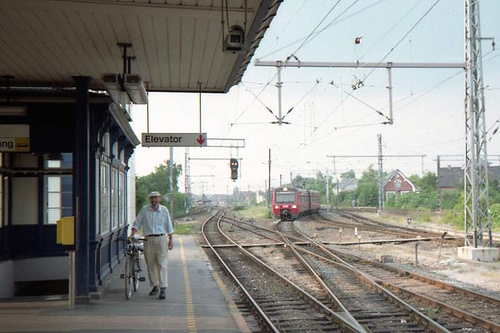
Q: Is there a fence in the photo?
A: No, there are no fences.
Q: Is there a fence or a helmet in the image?
A: No, there are no fences or helmets.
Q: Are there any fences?
A: No, there are no fences.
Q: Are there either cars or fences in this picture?
A: No, there are no fences or cars.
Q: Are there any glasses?
A: No, there are no glasses.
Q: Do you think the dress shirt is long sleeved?
A: Yes, the dress shirt is long sleeved.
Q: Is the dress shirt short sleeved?
A: No, the dress shirt is long sleeved.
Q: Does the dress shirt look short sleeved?
A: No, the dress shirt is long sleeved.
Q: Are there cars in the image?
A: No, there are no cars.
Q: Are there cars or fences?
A: No, there are no cars or fences.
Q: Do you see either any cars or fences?
A: No, there are no cars or fences.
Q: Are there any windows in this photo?
A: Yes, there are windows.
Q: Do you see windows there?
A: Yes, there are windows.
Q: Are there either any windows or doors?
A: Yes, there are windows.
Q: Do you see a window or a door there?
A: Yes, there are windows.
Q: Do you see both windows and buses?
A: No, there are windows but no buses.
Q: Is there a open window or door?
A: Yes, there are open windows.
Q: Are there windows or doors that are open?
A: Yes, the windows are open.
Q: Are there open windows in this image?
A: Yes, there are open windows.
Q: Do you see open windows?
A: Yes, there are open windows.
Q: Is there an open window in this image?
A: Yes, there are open windows.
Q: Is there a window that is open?
A: Yes, there are windows that are open.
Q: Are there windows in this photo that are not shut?
A: Yes, there are open windows.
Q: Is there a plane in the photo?
A: No, there are no airplanes.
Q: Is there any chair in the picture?
A: No, there are no chairs.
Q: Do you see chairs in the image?
A: No, there are no chairs.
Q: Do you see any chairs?
A: No, there are no chairs.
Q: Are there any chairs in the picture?
A: No, there are no chairs.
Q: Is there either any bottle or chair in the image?
A: No, there are no chairs or bottles.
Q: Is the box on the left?
A: Yes, the box is on the left of the image.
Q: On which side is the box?
A: The box is on the left of the image.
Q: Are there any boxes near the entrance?
A: Yes, there is a box near the entrance.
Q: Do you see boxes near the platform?
A: Yes, there is a box near the platform.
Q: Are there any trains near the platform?
A: No, there is a box near the platform.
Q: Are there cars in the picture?
A: No, there are no cars.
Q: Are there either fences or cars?
A: No, there are no cars or fences.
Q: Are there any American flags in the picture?
A: No, there are no American flags.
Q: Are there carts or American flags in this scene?
A: No, there are no American flags or carts.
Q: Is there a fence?
A: No, there are no fences.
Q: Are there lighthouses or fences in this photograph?
A: No, there are no fences or lighthouses.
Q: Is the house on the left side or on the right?
A: The house is on the right of the image.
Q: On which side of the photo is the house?
A: The house is on the right of the image.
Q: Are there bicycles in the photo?
A: Yes, there is a bicycle.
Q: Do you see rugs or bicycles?
A: Yes, there is a bicycle.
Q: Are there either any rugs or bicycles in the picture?
A: Yes, there is a bicycle.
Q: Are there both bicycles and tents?
A: No, there is a bicycle but no tents.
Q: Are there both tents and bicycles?
A: No, there is a bicycle but no tents.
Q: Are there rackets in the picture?
A: No, there are no rackets.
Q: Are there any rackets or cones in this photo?
A: No, there are no rackets or cones.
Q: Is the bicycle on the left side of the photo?
A: Yes, the bicycle is on the left of the image.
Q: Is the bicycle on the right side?
A: No, the bicycle is on the left of the image.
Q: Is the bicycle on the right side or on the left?
A: The bicycle is on the left of the image.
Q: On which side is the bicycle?
A: The bicycle is on the left of the image.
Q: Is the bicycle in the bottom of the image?
A: Yes, the bicycle is in the bottom of the image.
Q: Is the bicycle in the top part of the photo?
A: No, the bicycle is in the bottom of the image.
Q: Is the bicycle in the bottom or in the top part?
A: The bicycle is in the bottom of the image.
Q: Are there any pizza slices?
A: No, there are no pizza slices.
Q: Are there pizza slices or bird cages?
A: No, there are no pizza slices or bird cages.